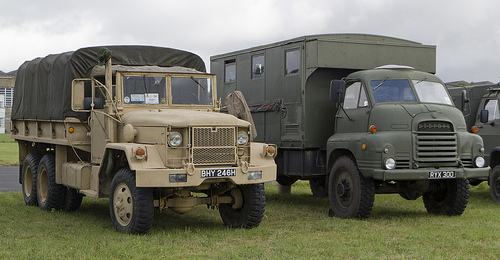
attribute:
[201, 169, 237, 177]
license plate — black, white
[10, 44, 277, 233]
truck — tan, large, army truck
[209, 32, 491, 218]
truck — green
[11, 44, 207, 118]
tarp — black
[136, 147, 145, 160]
light — orange, round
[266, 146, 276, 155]
light — orange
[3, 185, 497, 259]
grass — green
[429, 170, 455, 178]
license plate — black, white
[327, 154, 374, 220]
tire — black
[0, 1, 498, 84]
sky — cloudy, gray